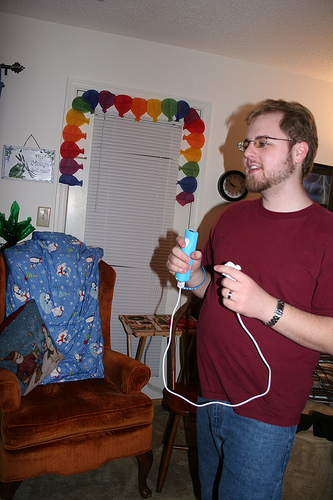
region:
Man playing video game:
[150, 95, 329, 497]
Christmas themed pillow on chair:
[2, 298, 65, 403]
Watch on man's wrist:
[266, 295, 285, 333]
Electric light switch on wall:
[33, 203, 52, 231]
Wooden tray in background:
[116, 309, 195, 400]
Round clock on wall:
[211, 168, 249, 205]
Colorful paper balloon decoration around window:
[40, 87, 206, 209]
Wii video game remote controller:
[160, 227, 275, 410]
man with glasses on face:
[233, 133, 309, 155]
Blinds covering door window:
[77, 108, 183, 384]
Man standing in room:
[191, 99, 331, 498]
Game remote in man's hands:
[165, 229, 269, 401]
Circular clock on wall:
[210, 166, 247, 202]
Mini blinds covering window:
[80, 102, 185, 385]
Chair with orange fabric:
[1, 252, 167, 499]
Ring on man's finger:
[225, 288, 235, 300]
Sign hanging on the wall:
[1, 132, 55, 189]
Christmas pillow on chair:
[0, 296, 66, 397]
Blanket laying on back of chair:
[5, 230, 106, 390]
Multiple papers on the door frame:
[34, 82, 211, 210]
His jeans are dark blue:
[189, 388, 308, 499]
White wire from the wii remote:
[146, 275, 286, 423]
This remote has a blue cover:
[152, 221, 199, 290]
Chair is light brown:
[0, 224, 160, 487]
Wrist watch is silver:
[255, 293, 296, 332]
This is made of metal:
[263, 294, 292, 330]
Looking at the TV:
[230, 121, 282, 156]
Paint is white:
[25, 27, 136, 61]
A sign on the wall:
[1, 128, 59, 199]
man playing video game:
[194, 98, 328, 498]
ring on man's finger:
[224, 290, 233, 299]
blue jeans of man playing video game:
[194, 400, 294, 499]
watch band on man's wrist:
[261, 297, 287, 327]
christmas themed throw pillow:
[5, 303, 63, 398]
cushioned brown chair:
[1, 244, 153, 492]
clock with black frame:
[216, 165, 248, 201]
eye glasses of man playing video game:
[234, 134, 289, 153]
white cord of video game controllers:
[156, 285, 269, 412]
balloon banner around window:
[58, 88, 207, 208]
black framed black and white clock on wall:
[213, 159, 252, 208]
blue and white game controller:
[159, 219, 273, 428]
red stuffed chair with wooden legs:
[0, 231, 152, 497]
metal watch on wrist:
[261, 289, 287, 334]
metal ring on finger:
[223, 287, 234, 301]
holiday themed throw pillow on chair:
[3, 294, 68, 402]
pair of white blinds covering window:
[83, 102, 187, 389]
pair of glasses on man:
[231, 130, 300, 158]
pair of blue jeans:
[188, 381, 302, 498]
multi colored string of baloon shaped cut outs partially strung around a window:
[57, 86, 206, 208]